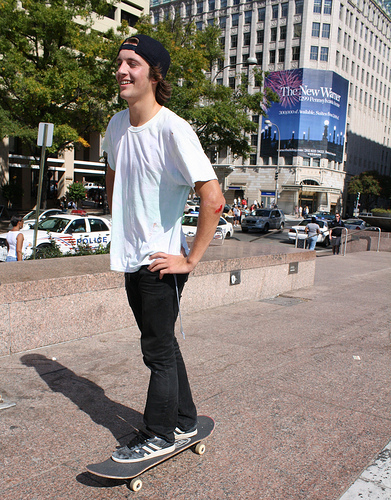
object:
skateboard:
[85, 413, 216, 491]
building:
[149, 1, 390, 218]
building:
[0, 0, 150, 214]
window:
[309, 45, 329, 62]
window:
[311, 21, 331, 39]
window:
[293, 22, 302, 37]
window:
[292, 46, 300, 60]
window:
[280, 25, 287, 39]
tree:
[1, 0, 129, 207]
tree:
[116, 11, 278, 186]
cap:
[117, 34, 171, 80]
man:
[100, 33, 225, 464]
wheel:
[36, 242, 55, 251]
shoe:
[111, 428, 175, 462]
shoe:
[172, 425, 198, 439]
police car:
[0, 209, 112, 261]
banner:
[259, 68, 350, 166]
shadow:
[19, 353, 147, 448]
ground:
[0, 251, 391, 495]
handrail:
[303, 226, 348, 256]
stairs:
[316, 247, 375, 258]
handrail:
[249, 226, 298, 248]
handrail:
[340, 226, 381, 253]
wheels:
[129, 441, 205, 491]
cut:
[214, 204, 222, 214]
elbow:
[200, 194, 227, 217]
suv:
[241, 207, 285, 233]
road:
[225, 220, 304, 254]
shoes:
[111, 422, 197, 463]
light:
[70, 208, 88, 216]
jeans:
[124, 264, 198, 445]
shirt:
[100, 105, 218, 273]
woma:
[304, 217, 320, 251]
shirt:
[306, 222, 319, 238]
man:
[329, 213, 349, 256]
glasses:
[335, 215, 340, 217]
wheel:
[129, 477, 142, 491]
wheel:
[195, 442, 206, 455]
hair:
[146, 61, 171, 105]